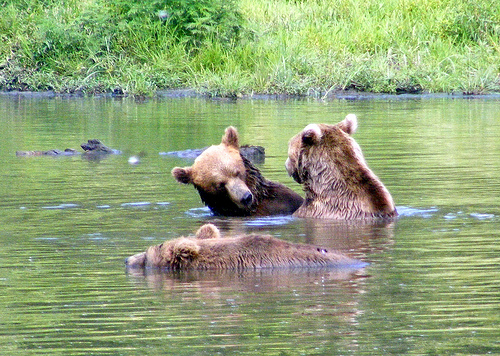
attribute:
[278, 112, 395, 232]
bear — brown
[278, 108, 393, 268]
bear — brown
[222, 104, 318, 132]
water — green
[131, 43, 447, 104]
bank — green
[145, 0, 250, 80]
leaves — green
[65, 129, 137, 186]
rocks — black, gray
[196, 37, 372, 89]
grass — green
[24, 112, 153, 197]
water — calm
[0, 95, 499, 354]
water — green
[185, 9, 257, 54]
bushes — green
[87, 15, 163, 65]
bushes — green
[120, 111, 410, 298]
three bears — brown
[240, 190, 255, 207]
nose — black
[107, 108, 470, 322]
bear — brown 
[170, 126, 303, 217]
bear — brown, wet